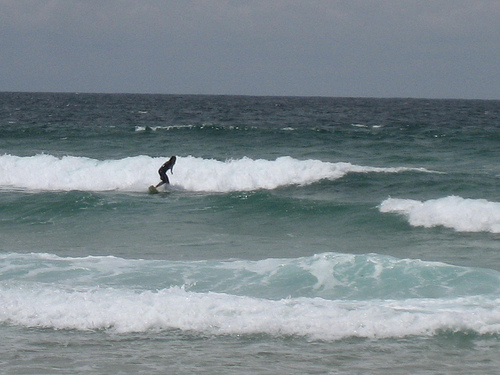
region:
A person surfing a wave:
[148, 157, 184, 192]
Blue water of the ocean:
[3, 90, 498, 356]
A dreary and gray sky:
[1, 0, 495, 111]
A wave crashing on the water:
[1, 248, 496, 340]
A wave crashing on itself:
[0, 145, 355, 198]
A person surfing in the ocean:
[151, 154, 180, 194]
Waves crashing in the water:
[373, 190, 499, 236]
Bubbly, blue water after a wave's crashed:
[288, 256, 446, 292]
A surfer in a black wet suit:
[144, 150, 179, 195]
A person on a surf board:
[150, 154, 178, 194]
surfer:
[135, 136, 182, 190]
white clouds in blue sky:
[345, 5, 427, 65]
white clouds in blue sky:
[184, 16, 218, 60]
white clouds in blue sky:
[281, 21, 308, 56]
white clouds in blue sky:
[7, 8, 45, 45]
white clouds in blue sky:
[98, 33, 132, 58]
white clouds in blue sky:
[401, 19, 441, 46]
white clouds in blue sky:
[262, 19, 312, 81]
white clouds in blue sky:
[165, 22, 230, 87]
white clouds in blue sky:
[44, 12, 94, 59]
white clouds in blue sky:
[335, 39, 380, 67]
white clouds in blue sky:
[350, 39, 394, 66]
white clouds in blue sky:
[322, 38, 354, 62]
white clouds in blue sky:
[254, 1, 296, 39]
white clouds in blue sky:
[251, 23, 325, 63]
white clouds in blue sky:
[187, 23, 257, 67]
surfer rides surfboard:
[146, 155, 178, 195]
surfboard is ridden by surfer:
[145, 185, 161, 195]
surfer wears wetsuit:
[149, 153, 176, 196]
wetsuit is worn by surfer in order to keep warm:
[156, 156, 176, 184]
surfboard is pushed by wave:
[145, 180, 160, 190]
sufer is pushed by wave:
[155, 155, 176, 190]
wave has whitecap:
[0, 151, 421, 196]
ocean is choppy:
[0, 91, 496, 372]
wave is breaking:
[0, 155, 370, 198]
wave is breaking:
[1, 248, 495, 339]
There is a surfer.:
[146, 148, 181, 200]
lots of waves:
[8, 151, 375, 193]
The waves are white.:
[10, 252, 481, 332]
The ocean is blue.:
[250, 105, 465, 148]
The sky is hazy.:
[6, 6, 491, 96]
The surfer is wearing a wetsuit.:
[156, 157, 172, 184]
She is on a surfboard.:
[145, 150, 181, 195]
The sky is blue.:
[12, 10, 493, 80]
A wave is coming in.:
[5, 152, 347, 192]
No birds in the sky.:
[21, 14, 498, 92]